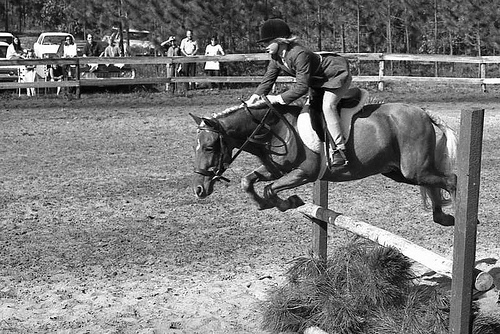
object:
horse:
[187, 100, 480, 226]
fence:
[296, 106, 483, 333]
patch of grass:
[268, 242, 450, 334]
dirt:
[0, 97, 500, 334]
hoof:
[288, 195, 305, 209]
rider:
[240, 19, 353, 168]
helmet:
[255, 20, 292, 43]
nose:
[191, 180, 215, 199]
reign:
[194, 99, 278, 183]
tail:
[421, 109, 459, 212]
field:
[0, 62, 500, 334]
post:
[449, 107, 484, 334]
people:
[5, 29, 225, 97]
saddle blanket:
[298, 87, 370, 156]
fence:
[0, 52, 500, 95]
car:
[33, 33, 77, 59]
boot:
[331, 150, 348, 168]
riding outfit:
[254, 43, 352, 168]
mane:
[198, 104, 281, 126]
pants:
[322, 72, 355, 153]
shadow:
[402, 254, 500, 294]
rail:
[296, 202, 493, 292]